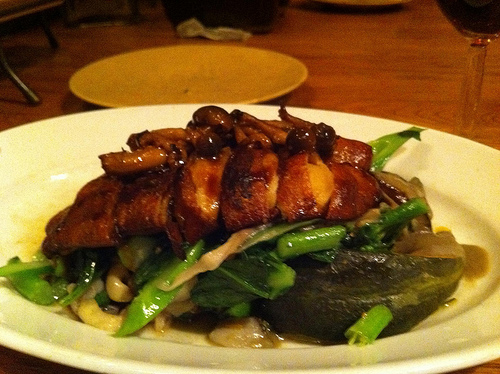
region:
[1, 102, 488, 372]
Meat and vegetables on white plate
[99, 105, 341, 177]
Mushrooms on meat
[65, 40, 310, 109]
Tan plate on table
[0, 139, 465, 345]
Meat on vegetables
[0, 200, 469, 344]
Cooked green vegetables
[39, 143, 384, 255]
Cooked meat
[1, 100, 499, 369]
White plate on a table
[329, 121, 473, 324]
food in a plate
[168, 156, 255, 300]
food in a plate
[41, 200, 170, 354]
food in a plate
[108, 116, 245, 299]
food in a plate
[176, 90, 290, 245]
food in a plate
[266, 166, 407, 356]
food in a plate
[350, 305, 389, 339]
GREEN BEANS ON THE PLATE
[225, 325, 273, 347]
SAUCE ON THE PLATE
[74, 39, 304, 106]
SAUCER ON THE TABLE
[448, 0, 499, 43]
WINE IN THE GLASS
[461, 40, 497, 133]
GLASS ON THE TABLE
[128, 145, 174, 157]
MUSHROOMS ON THE TOP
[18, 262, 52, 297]
GREEN LEAF ON THE PLATE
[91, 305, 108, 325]
ONIONS ON THE PLATE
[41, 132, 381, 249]
a piece of braised pork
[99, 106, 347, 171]
sauteed mushrooms on top of pork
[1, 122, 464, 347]
vegetable greens and noodles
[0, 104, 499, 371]
an oval white plate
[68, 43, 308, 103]
a round brown plate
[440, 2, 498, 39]
red wine inside a glass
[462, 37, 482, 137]
the clear stem of a wine glass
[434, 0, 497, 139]
a glass of red wine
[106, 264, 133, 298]
the bent end of a white noodle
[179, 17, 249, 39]
a small twisted piece of plastic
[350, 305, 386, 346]
bean on a plate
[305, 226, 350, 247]
bean on a plate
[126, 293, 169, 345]
bean on a plate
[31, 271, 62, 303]
bean on a plate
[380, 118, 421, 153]
bean on a plate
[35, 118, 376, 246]
meat on a plate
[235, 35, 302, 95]
plate on a table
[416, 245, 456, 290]
vegetable on a plate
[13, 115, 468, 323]
food on a plate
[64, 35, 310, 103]
the brown saucer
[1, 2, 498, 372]
the wooden table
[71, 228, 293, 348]
the shallots on plate